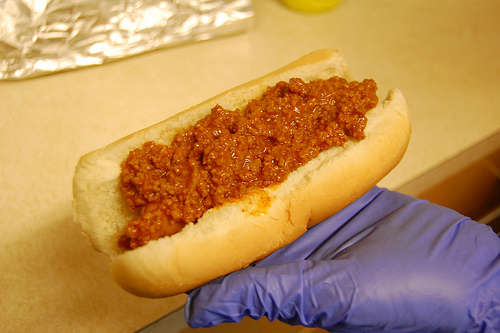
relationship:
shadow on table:
[0, 216, 190, 331] [2, 2, 497, 331]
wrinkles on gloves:
[183, 185, 496, 332] [181, 178, 497, 331]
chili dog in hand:
[119, 62, 372, 209] [180, 184, 485, 331]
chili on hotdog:
[116, 70, 379, 251] [54, 47, 417, 302]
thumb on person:
[184, 261, 354, 328] [194, 188, 479, 320]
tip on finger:
[184, 284, 234, 330] [184, 267, 359, 319]